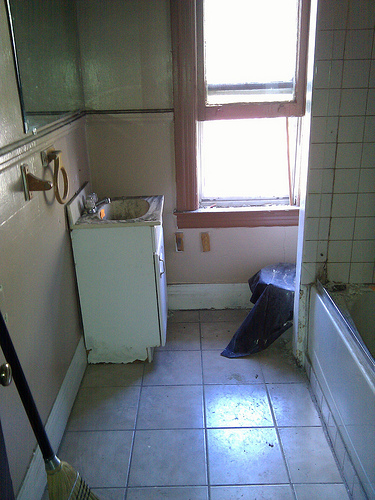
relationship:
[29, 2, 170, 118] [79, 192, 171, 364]
mirror above vanity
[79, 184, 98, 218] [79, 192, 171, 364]
knobs on vanity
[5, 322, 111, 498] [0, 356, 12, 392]
broom near handle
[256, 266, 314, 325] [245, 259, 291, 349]
cover on toilet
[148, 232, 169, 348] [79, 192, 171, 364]
door on vanity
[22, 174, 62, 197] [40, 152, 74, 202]
hook near ring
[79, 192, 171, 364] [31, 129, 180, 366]
vanity on wall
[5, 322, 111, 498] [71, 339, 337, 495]
broom on floor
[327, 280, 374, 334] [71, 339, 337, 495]
tub near floor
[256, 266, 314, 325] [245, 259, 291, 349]
cover over toilet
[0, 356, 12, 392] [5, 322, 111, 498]
handle near broom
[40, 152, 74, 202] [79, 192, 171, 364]
ring near vanity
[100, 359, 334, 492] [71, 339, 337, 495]
tile on floor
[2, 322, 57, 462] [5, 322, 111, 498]
handle on broom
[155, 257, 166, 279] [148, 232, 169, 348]
handle on door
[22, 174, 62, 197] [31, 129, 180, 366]
hook on wall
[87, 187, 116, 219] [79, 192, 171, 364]
faucet on vanity